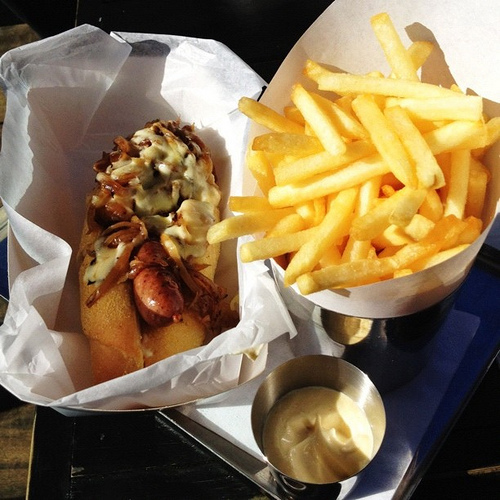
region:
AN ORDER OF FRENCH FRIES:
[206, 8, 493, 319]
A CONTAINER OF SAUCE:
[246, 351, 392, 490]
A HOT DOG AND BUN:
[48, 86, 232, 371]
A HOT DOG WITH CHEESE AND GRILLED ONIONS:
[71, 99, 233, 379]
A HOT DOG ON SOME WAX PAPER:
[9, 29, 266, 396]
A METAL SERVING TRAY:
[137, 242, 498, 493]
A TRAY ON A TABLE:
[92, 266, 497, 496]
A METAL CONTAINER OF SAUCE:
[227, 346, 396, 498]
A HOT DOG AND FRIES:
[32, 67, 489, 387]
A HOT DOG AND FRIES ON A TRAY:
[16, 18, 496, 482]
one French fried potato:
[290, 83, 340, 153]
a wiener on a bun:
[130, 235, 178, 323]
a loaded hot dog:
[79, 106, 221, 368]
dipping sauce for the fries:
[247, 350, 399, 487]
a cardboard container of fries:
[238, 0, 498, 320]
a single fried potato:
[287, 81, 345, 153]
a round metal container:
[242, 346, 392, 485]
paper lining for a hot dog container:
[0, 22, 294, 415]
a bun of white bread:
[80, 240, 223, 372]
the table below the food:
[0, 403, 27, 493]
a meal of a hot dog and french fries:
[50, 21, 483, 381]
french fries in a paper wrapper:
[255, 52, 481, 292]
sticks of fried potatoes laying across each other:
[261, 55, 472, 306]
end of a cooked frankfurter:
[105, 252, 210, 332]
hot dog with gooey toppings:
[20, 75, 265, 380]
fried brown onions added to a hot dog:
[81, 95, 218, 350]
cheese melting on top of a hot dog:
[80, 101, 215, 376]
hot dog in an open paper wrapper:
[20, 26, 276, 396]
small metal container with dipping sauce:
[236, 340, 396, 490]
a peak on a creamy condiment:
[257, 365, 377, 486]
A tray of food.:
[5, 20, 493, 490]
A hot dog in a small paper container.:
[6, 42, 276, 422]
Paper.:
[25, 70, 100, 132]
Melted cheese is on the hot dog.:
[112, 126, 199, 261]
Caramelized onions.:
[90, 135, 145, 282]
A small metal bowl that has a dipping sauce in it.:
[242, 351, 392, 496]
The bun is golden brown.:
[75, 290, 135, 370]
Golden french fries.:
[295, 82, 450, 259]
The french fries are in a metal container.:
[235, 45, 480, 385]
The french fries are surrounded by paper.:
[240, 5, 496, 320]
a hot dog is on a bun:
[77, 112, 215, 377]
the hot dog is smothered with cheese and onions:
[78, 115, 215, 330]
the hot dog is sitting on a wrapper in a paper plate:
[0, 26, 286, 413]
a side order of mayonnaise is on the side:
[247, 350, 383, 496]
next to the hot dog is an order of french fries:
[210, 17, 495, 293]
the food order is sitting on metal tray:
[1, 5, 492, 486]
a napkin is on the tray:
[166, 291, 478, 496]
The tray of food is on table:
[8, 5, 488, 490]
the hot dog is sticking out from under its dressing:
[125, 235, 187, 330]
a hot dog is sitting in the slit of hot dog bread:
[80, 233, 220, 382]